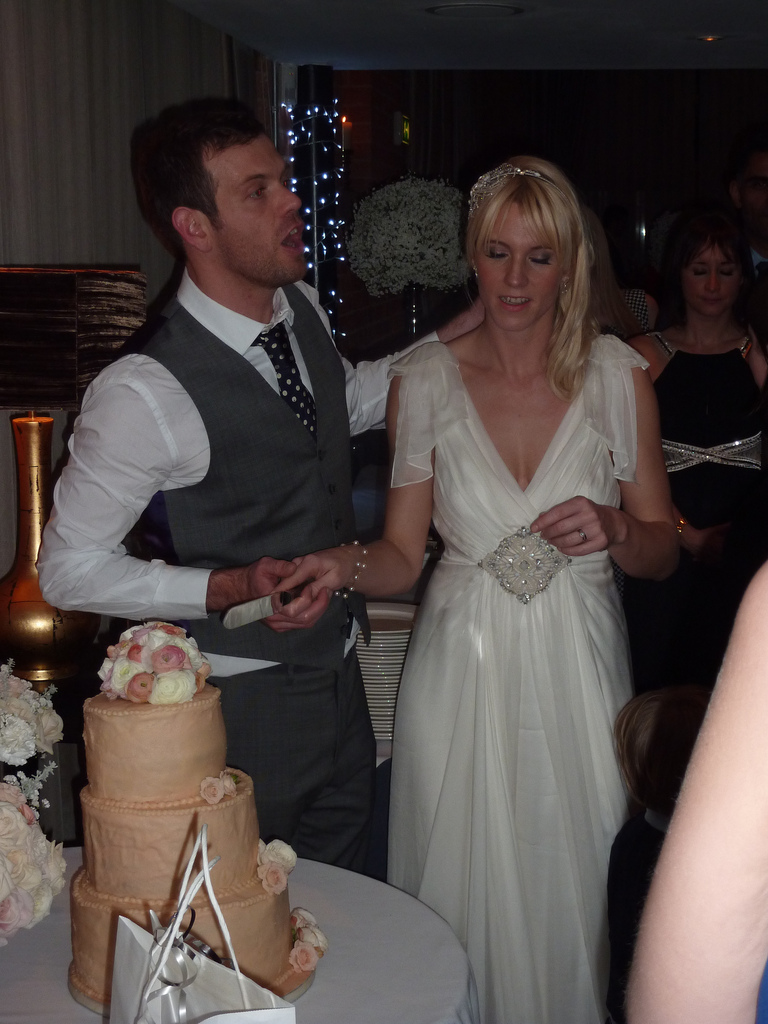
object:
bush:
[344, 175, 473, 296]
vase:
[406, 284, 420, 344]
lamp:
[0, 405, 102, 679]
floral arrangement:
[0, 657, 69, 945]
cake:
[71, 614, 326, 1011]